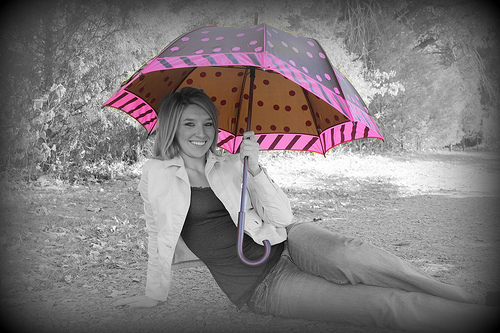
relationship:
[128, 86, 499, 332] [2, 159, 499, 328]
girl on ground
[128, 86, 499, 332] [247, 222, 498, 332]
girl with legs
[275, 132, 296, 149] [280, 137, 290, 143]
stripes on pink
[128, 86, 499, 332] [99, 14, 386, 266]
girl holding umbrella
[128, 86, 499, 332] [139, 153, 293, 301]
girl wearing jacket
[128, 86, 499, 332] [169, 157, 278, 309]
girl wearing shirt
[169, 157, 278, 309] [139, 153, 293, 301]
shirt under jacket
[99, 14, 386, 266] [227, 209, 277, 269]
umbrella with handle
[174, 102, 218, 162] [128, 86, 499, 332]
face of girl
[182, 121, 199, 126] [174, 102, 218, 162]
eye on face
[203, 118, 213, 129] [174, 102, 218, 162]
eye on face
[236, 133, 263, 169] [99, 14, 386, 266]
hand holding umbrella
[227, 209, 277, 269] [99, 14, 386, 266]
handle of umbrella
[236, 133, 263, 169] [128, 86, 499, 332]
hand of girl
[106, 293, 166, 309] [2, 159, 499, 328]
hand on ground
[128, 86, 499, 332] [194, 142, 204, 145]
girl with smile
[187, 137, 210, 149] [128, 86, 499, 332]
mouth of girl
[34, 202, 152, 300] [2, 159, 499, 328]
leaves on ground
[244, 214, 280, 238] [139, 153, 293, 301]
pocket of jacket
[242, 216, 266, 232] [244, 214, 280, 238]
flap of pocket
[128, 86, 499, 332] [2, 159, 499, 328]
woman on ground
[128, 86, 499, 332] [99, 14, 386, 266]
woman holding umbrella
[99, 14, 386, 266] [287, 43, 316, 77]
umbrella has dots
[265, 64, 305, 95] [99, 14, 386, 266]
edge of umbrella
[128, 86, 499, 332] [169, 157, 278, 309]
woman wearing shirt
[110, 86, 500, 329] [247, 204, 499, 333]
girl wearing pants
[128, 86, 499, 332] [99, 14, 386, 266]
lady with umbrella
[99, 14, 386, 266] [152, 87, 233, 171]
umbrella over head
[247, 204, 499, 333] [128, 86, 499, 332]
pants on lady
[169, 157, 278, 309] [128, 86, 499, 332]
shirt on lady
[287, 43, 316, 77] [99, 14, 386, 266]
dots on umbrella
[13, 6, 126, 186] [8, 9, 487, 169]
tree in background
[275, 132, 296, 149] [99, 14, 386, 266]
stripes on umbrella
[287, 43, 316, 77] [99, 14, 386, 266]
circles on umbrella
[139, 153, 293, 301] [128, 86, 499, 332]
jacket on woman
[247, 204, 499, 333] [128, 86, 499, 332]
pants on woman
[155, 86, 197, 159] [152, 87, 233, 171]
hair on head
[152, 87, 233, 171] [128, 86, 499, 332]
head of woman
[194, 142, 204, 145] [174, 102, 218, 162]
smile on face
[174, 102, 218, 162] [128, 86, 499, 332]
face of woman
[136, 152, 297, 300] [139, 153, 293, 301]
jacket worn by jacket